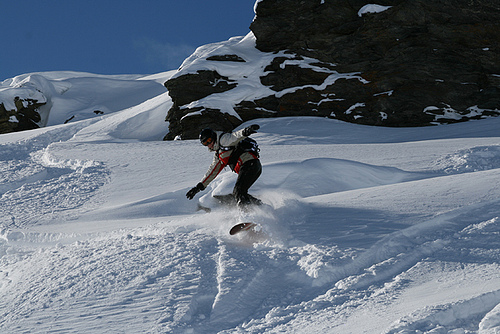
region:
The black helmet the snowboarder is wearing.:
[199, 131, 211, 139]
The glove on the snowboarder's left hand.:
[183, 186, 198, 198]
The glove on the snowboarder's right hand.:
[239, 124, 259, 132]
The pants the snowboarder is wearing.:
[227, 163, 262, 203]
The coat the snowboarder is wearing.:
[207, 138, 258, 173]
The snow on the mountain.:
[0, 36, 384, 137]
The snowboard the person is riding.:
[232, 220, 266, 233]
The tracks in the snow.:
[8, 156, 335, 332]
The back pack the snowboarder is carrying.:
[238, 135, 261, 155]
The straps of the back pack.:
[212, 132, 232, 157]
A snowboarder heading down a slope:
[177, 113, 304, 259]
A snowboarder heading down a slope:
[181, 118, 283, 249]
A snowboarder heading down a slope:
[182, 117, 278, 258]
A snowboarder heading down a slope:
[179, 116, 276, 251]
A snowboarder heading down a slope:
[183, 114, 275, 247]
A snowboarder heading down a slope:
[178, 113, 270, 251]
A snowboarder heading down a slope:
[184, 118, 277, 248]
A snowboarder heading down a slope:
[178, 118, 290, 248]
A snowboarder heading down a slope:
[175, 112, 277, 242]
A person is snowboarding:
[173, 112, 290, 247]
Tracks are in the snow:
[148, 197, 499, 332]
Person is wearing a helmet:
[192, 120, 219, 155]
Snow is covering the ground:
[9, 102, 496, 333]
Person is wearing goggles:
[194, 125, 220, 157]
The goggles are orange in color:
[188, 122, 220, 156]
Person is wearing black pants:
[221, 155, 265, 231]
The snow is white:
[1, 123, 499, 333]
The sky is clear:
[0, 0, 255, 85]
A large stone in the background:
[153, 1, 498, 139]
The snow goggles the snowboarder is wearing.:
[196, 134, 217, 141]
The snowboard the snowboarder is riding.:
[222, 221, 262, 234]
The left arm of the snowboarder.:
[192, 159, 225, 194]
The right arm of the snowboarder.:
[222, 128, 260, 143]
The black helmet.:
[198, 131, 213, 135]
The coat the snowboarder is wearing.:
[190, 136, 255, 169]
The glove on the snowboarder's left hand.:
[182, 185, 203, 197]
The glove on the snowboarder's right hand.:
[242, 126, 262, 133]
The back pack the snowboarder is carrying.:
[225, 132, 260, 155]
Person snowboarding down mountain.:
[180, 118, 274, 243]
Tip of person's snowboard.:
[223, 219, 258, 236]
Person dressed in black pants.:
[230, 160, 266, 210]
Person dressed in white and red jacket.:
[194, 127, 263, 189]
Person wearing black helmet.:
[195, 127, 220, 141]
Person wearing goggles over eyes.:
[199, 134, 216, 148]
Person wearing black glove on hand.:
[183, 177, 209, 206]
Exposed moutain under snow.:
[156, 62, 281, 142]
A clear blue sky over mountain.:
[38, 19, 125, 55]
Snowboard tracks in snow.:
[336, 191, 488, 331]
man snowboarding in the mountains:
[165, 99, 282, 256]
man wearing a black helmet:
[153, 108, 278, 236]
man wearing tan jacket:
[176, 108, 288, 238]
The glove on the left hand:
[242, 121, 264, 136]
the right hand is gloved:
[184, 181, 204, 201]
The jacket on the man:
[199, 125, 257, 187]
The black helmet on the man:
[199, 127, 219, 143]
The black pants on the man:
[231, 153, 265, 209]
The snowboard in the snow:
[228, 221, 253, 238]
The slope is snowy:
[1, 117, 498, 329]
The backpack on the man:
[237, 133, 259, 155]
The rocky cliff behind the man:
[162, 0, 499, 141]